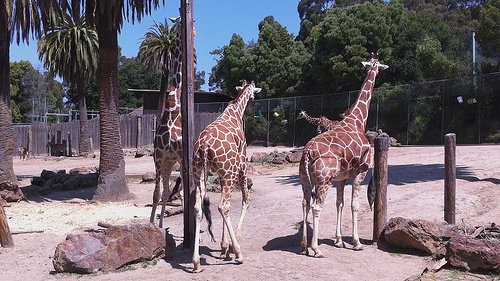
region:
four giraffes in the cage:
[102, 16, 471, 279]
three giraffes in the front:
[151, 11, 426, 263]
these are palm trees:
[21, 10, 181, 204]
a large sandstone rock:
[33, 175, 183, 274]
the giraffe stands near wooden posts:
[290, 14, 495, 237]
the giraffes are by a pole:
[136, 9, 269, 279]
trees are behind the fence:
[218, 25, 478, 270]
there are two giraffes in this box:
[115, 16, 283, 270]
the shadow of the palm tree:
[22, 149, 152, 209]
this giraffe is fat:
[283, 29, 414, 256]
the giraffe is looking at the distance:
[302, 55, 387, 256]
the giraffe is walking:
[190, 76, 262, 269]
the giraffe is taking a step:
[196, 78, 257, 265]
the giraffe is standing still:
[304, 57, 384, 249]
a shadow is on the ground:
[266, 211, 374, 261]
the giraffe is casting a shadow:
[267, 218, 379, 259]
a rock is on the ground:
[55, 215, 174, 269]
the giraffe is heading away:
[191, 79, 259, 262]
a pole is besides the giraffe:
[437, 133, 460, 224]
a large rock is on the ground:
[56, 216, 170, 267]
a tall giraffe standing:
[287, 49, 381, 251]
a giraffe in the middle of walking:
[195, 65, 272, 260]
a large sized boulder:
[42, 193, 186, 275]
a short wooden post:
[421, 129, 473, 229]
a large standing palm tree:
[51, 1, 159, 215]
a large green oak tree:
[212, 28, 322, 95]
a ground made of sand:
[248, 222, 309, 274]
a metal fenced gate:
[405, 61, 497, 122]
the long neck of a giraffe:
[335, 69, 400, 129]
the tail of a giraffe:
[287, 128, 327, 203]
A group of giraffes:
[180, 40, 414, 279]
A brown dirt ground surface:
[260, 169, 292, 226]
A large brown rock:
[45, 206, 180, 278]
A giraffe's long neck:
[342, 68, 387, 122]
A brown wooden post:
[433, 123, 473, 225]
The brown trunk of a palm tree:
[90, 88, 136, 205]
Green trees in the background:
[226, 1, 482, 62]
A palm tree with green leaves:
[27, 18, 123, 169]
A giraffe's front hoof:
[348, 232, 368, 254]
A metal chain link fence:
[253, 90, 298, 145]